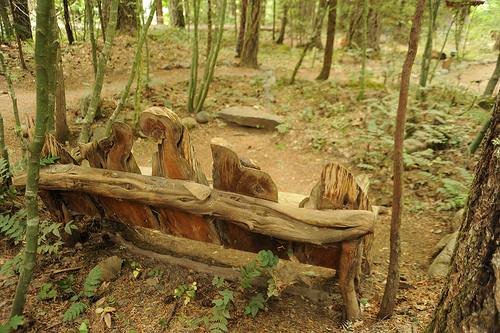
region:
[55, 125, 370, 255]
this is a bench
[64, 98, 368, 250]
the bench is wooden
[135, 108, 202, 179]
this is a log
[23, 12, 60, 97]
the stem is thin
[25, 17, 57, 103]
the stem is green in color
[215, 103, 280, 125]
this is a rock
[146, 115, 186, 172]
the log is brown in color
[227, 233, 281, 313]
the leaves are green in color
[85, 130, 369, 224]
the bench is empty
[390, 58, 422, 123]
the stem is weak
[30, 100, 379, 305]
custom made wooden bench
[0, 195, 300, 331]
shrubbery behind the bench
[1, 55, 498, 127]
trail leading through the forest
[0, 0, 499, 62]
many trees in the distant background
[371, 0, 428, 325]
skinny tree trunk next to bench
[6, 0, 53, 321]
green skinny tree trunk behind bench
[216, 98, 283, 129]
big rock on the ground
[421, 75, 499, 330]
big tree trunk on the side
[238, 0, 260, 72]
tall and big tree trunk next to the trail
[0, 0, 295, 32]
light peeking through the forest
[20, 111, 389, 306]
a wooden bench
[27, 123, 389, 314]
a man made wood bench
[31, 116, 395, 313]
a bench made of wood in the woods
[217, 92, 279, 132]
a large rock in front of the bench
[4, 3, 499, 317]
trees surrounding a wooden bench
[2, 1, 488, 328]
wooden bench in the woods surrounded by trees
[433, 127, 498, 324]
bark of a tree trunk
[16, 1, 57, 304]
tall green root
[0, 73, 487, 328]
weeds on the ground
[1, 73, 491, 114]
a small pathway on the ground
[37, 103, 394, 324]
wooden bench in forest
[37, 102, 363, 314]
bench made from reclaimed wood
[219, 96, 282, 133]
rock in front of wooden bench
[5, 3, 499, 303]
tree trunks in forest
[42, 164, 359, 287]
logs forms support on back of chair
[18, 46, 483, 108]
path through the woods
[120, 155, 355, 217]
seat of wooden bench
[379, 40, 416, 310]
sapling next to wooden bench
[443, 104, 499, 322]
tree trunk in right corner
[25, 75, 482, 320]
plants growing on forest floor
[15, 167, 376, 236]
Long wooden log in the forest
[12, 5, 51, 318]
Tall green stalk in the forest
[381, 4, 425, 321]
Tall tree branch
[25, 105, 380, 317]
Old bench made out of wood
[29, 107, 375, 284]
Back of the bench used for resting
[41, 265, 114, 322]
Group of small green leaves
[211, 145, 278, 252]
Small wooden plank on the bench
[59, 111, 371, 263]
group of wooden plank that makes up the bench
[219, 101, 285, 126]
Large rock on the ground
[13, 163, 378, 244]
Log connecting the planks together